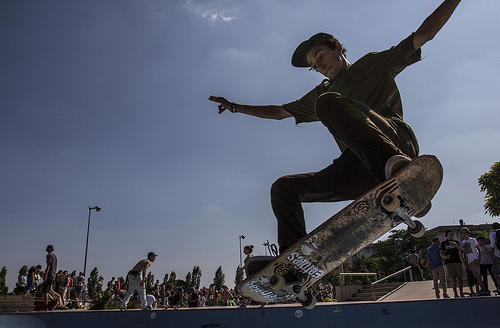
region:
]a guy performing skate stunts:
[179, 16, 481, 309]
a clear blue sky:
[67, 71, 175, 146]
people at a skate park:
[21, 241, 254, 308]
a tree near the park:
[480, 157, 498, 214]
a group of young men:
[424, 226, 488, 289]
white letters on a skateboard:
[283, 251, 323, 281]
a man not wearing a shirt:
[120, 249, 164, 308]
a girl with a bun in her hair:
[241, 241, 258, 260]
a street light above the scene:
[74, 194, 108, 267]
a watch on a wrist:
[221, 102, 248, 118]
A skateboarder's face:
[290, 33, 355, 80]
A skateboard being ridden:
[234, 152, 470, 317]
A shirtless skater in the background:
[122, 247, 155, 309]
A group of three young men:
[426, 224, 488, 298]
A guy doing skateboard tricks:
[201, 13, 452, 298]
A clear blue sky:
[17, 62, 278, 263]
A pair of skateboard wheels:
[373, 188, 431, 243]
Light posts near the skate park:
[67, 194, 277, 286]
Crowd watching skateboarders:
[24, 255, 237, 311]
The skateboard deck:
[255, 214, 425, 297]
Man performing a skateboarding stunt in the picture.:
[209, 0, 463, 308]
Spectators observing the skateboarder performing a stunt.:
[439, 221, 499, 296]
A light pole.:
[82, 205, 102, 275]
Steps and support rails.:
[337, 266, 415, 301]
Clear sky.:
[7, 11, 197, 116]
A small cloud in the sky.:
[194, 4, 243, 34]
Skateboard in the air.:
[237, 154, 444, 310]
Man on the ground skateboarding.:
[119, 250, 157, 311]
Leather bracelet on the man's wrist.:
[207, 94, 245, 119]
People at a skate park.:
[1, 219, 498, 296]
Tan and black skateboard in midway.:
[228, 153, 444, 308]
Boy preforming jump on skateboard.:
[200, 1, 459, 255]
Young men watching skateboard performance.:
[427, 226, 499, 293]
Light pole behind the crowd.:
[84, 203, 99, 279]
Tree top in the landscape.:
[477, 157, 499, 216]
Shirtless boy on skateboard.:
[115, 250, 160, 310]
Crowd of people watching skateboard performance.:
[15, 264, 230, 307]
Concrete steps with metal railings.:
[337, 264, 414, 306]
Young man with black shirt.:
[439, 228, 466, 300]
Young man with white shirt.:
[459, 227, 482, 296]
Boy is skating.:
[231, 31, 432, 301]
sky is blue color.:
[64, 62, 170, 145]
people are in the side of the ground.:
[11, 241, 213, 303]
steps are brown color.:
[343, 271, 408, 302]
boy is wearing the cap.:
[284, 29, 340, 68]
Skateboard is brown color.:
[232, 168, 439, 306]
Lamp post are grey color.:
[84, 198, 101, 287]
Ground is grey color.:
[364, 306, 417, 327]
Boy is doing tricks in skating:
[256, 37, 449, 301]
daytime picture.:
[25, 49, 456, 308]